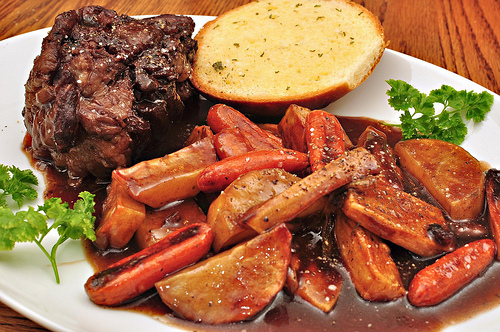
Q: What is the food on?
A: Plate.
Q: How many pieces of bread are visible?
A: One.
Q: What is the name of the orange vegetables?
A: Carrots.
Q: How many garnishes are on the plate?
A: Two.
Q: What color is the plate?
A: White.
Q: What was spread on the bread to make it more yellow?
A: Butter.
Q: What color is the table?
A: Brown.